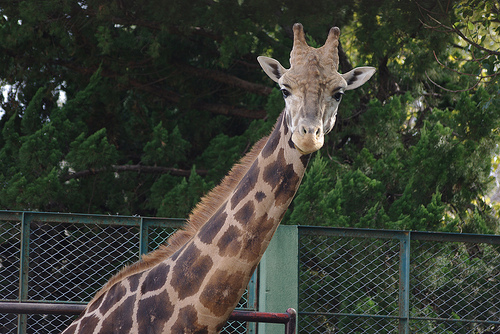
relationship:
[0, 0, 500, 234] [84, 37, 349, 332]
branch near girafee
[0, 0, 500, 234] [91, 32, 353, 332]
branch near giraffe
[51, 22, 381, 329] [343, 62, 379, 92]
giraffe has ear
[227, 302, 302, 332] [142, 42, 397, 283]
red bar by giraffe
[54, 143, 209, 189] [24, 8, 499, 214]
branch in tree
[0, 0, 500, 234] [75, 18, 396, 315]
branch behind giraffe.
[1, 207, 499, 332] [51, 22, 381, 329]
fence behind giraffe